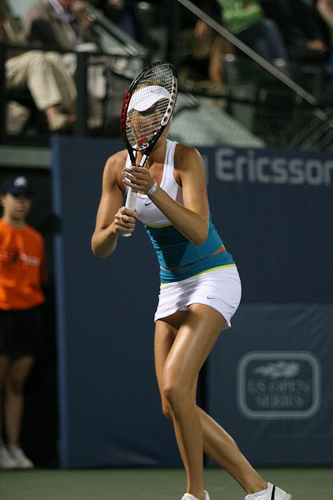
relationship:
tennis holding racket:
[91, 76, 292, 500] [120, 59, 179, 238]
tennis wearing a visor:
[91, 76, 292, 500] [124, 85, 173, 113]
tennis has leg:
[91, 76, 292, 500] [158, 266, 239, 498]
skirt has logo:
[150, 267, 255, 332] [206, 295, 217, 299]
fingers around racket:
[115, 207, 140, 237] [123, 58, 178, 242]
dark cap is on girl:
[1, 173, 33, 197] [0, 170, 50, 474]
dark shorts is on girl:
[0, 305, 40, 359] [0, 170, 50, 474]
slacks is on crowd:
[0, 47, 77, 109] [0, 0, 134, 143]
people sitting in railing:
[5, 7, 329, 131] [0, 43, 332, 147]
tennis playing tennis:
[91, 76, 292, 500] [102, 57, 250, 483]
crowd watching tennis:
[6, 14, 134, 119] [87, 57, 288, 473]